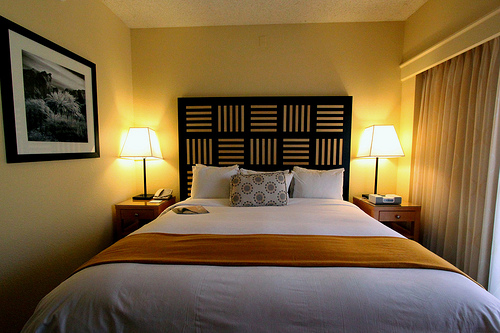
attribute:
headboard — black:
[169, 82, 368, 197]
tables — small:
[132, 185, 417, 219]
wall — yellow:
[136, 22, 409, 95]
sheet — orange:
[58, 231, 477, 270]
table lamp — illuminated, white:
[356, 127, 403, 195]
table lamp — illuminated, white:
[117, 126, 164, 203]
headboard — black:
[177, 95, 352, 167]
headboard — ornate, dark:
[172, 93, 354, 198]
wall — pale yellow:
[133, 16, 424, 213]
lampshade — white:
[355, 125, 405, 202]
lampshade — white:
[118, 126, 163, 199]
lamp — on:
[322, 106, 414, 211]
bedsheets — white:
[95, 208, 493, 332]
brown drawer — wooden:
[113, 194, 173, 241]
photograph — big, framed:
[4, 61, 71, 163]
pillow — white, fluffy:
[182, 163, 239, 203]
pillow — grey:
[224, 168, 289, 206]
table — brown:
[352, 192, 422, 242]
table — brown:
[109, 195, 174, 235]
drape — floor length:
[407, 38, 498, 298]